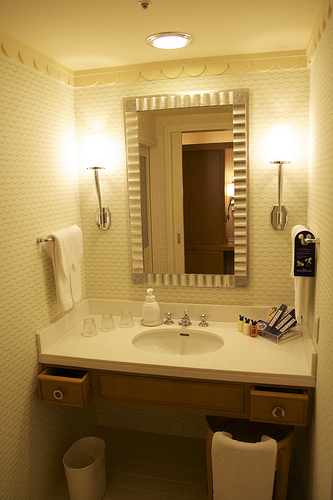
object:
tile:
[161, 464, 171, 480]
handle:
[271, 405, 287, 419]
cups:
[80, 312, 98, 341]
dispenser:
[140, 284, 163, 326]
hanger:
[292, 223, 313, 276]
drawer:
[249, 382, 309, 424]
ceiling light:
[148, 33, 192, 50]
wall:
[0, 32, 99, 496]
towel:
[47, 231, 82, 304]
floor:
[48, 423, 228, 499]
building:
[0, 2, 331, 499]